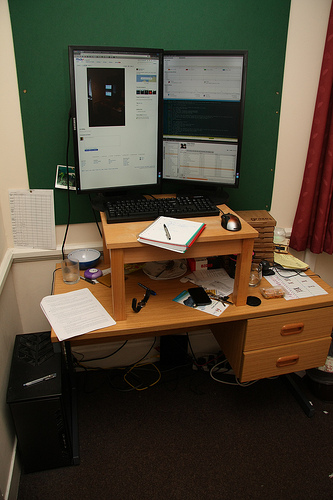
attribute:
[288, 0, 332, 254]
curtain — red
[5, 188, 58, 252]
paper — hanging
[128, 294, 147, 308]
watch — Black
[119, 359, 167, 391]
cord — Yellow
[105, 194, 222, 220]
keyboard — black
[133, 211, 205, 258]
pad — of paper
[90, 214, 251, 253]
desk — for computers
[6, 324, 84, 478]
processor — Black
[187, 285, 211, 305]
cellphone — Black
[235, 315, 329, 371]
drawer — Wooden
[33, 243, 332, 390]
desk — wooden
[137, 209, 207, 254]
notebook — White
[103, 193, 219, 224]
keyboard — Black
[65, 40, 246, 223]
display — unusual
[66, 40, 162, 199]
monitor — verticle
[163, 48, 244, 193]
monitor — verticle